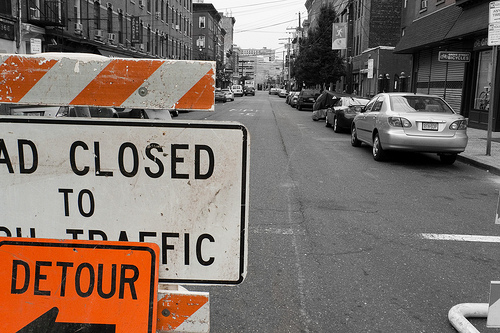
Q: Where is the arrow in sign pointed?
A: Left.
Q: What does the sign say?
A: Detour.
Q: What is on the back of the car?
A: License plate.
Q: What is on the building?
A: Sign.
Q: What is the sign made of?
A: Wood.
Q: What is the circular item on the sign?
A: Bolt.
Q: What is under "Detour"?
A: Arrow.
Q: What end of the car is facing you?
A: Back end.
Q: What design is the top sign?
A: Stripes.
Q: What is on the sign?
A: Word closed on sign.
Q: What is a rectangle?
A: Rectangle sign is white.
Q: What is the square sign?
A: Orange detour sign is square.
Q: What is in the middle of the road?
A: Line down middle of road.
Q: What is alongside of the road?
A: Buildings alongside of road.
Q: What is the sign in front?
A: Orange and black detour sign.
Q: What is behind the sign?
A: Orange and white traffic barrier.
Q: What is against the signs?
A: Detour signed leaned against other signs.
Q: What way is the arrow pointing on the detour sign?
A: Left.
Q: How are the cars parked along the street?
A: Parallel.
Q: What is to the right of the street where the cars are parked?
A: The sidewalk.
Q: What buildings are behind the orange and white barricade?
A: Apartments.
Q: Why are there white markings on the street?
A: To designate construction.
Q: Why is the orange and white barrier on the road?
A: To show the road is closed.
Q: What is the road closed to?
A: Traffic.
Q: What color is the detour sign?
A: Orange.